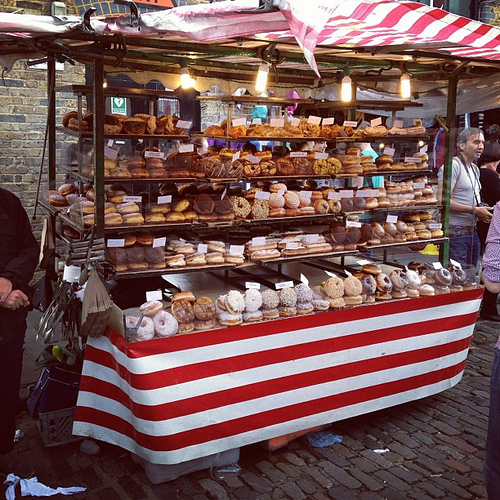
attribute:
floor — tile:
[16, 316, 498, 498]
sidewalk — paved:
[3, 273, 495, 494]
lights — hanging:
[173, 61, 418, 105]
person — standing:
[0, 185, 41, 498]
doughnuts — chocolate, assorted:
[189, 195, 236, 222]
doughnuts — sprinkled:
[216, 285, 263, 326]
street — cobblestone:
[0, 261, 494, 500]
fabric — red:
[139, 1, 498, 61]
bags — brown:
[78, 269, 114, 339]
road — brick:
[3, 321, 497, 500]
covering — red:
[1, 0, 499, 65]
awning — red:
[2, 1, 496, 77]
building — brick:
[0, 1, 500, 285]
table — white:
[85, 255, 476, 340]